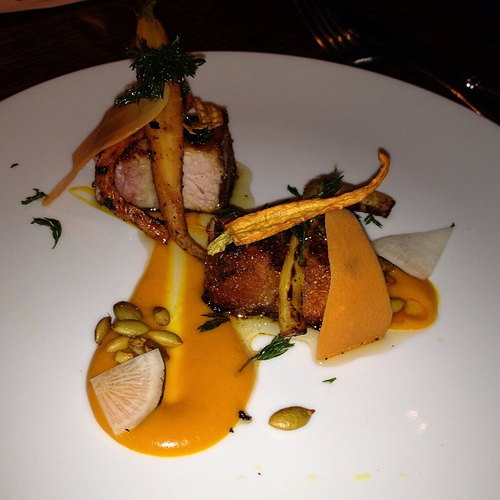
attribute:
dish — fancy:
[1, 51, 498, 498]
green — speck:
[306, 357, 351, 395]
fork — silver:
[317, 44, 494, 146]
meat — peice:
[98, 113, 237, 217]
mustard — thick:
[135, 292, 286, 419]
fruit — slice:
[87, 346, 170, 433]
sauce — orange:
[75, 58, 277, 466]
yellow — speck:
[343, 260, 373, 305]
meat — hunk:
[110, 106, 236, 209]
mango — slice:
[315, 194, 395, 365]